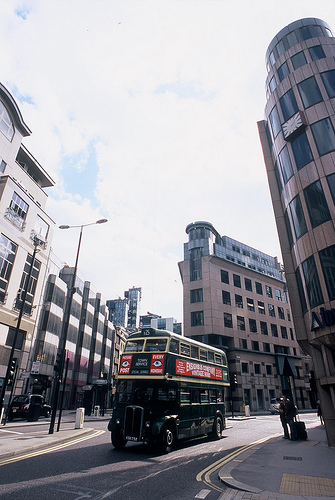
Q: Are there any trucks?
A: No, there are no trucks.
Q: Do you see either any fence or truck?
A: No, there are no trucks or fences.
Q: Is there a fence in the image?
A: No, there are no fences.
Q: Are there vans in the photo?
A: No, there are no vans.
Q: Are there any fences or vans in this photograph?
A: No, there are no vans or fences.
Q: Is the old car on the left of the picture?
A: Yes, the car is on the left of the image.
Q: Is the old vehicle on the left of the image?
A: Yes, the car is on the left of the image.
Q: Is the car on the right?
A: No, the car is on the left of the image.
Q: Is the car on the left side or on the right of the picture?
A: The car is on the left of the image.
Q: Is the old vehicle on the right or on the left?
A: The car is on the left of the image.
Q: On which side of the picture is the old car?
A: The car is on the left of the image.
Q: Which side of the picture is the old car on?
A: The car is on the left of the image.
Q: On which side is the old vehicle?
A: The car is on the left of the image.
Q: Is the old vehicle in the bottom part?
A: Yes, the car is in the bottom of the image.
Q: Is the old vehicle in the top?
A: No, the car is in the bottom of the image.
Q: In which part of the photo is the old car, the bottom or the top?
A: The car is in the bottom of the image.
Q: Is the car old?
A: Yes, the car is old.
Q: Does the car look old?
A: Yes, the car is old.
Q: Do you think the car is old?
A: Yes, the car is old.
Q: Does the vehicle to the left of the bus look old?
A: Yes, the car is old.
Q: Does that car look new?
A: No, the car is old.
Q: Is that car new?
A: No, the car is old.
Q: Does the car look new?
A: No, the car is old.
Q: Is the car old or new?
A: The car is old.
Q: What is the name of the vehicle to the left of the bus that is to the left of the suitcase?
A: The vehicle is a car.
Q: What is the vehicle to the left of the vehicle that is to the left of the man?
A: The vehicle is a car.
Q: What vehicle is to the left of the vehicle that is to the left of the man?
A: The vehicle is a car.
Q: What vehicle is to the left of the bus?
A: The vehicle is a car.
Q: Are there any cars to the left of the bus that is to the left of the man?
A: Yes, there is a car to the left of the bus.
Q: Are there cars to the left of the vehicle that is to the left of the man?
A: Yes, there is a car to the left of the bus.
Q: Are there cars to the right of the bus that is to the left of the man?
A: No, the car is to the left of the bus.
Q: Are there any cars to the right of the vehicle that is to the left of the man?
A: No, the car is to the left of the bus.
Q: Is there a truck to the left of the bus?
A: No, there is a car to the left of the bus.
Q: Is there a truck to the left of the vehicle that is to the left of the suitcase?
A: No, there is a car to the left of the bus.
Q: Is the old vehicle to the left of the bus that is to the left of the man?
A: Yes, the car is to the left of the bus.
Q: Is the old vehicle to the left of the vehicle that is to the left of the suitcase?
A: Yes, the car is to the left of the bus.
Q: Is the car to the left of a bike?
A: No, the car is to the left of the bus.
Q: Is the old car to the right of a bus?
A: No, the car is to the left of a bus.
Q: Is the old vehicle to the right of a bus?
A: No, the car is to the left of a bus.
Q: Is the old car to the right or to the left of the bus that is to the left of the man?
A: The car is to the left of the bus.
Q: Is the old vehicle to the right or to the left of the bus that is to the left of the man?
A: The car is to the left of the bus.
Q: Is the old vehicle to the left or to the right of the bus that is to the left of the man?
A: The car is to the left of the bus.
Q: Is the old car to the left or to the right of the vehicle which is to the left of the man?
A: The car is to the left of the bus.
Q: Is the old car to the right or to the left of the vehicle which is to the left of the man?
A: The car is to the left of the bus.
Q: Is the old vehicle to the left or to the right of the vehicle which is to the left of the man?
A: The car is to the left of the bus.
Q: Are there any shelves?
A: No, there are no shelves.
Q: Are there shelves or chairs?
A: No, there are no shelves or chairs.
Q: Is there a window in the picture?
A: Yes, there are windows.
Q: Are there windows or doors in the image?
A: Yes, there are windows.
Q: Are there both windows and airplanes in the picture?
A: No, there are windows but no airplanes.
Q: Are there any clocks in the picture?
A: Yes, there is a clock.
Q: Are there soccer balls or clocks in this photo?
A: Yes, there is a clock.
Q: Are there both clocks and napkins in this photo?
A: No, there is a clock but no napkins.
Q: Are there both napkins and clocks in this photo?
A: No, there is a clock but no napkins.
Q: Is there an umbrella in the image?
A: No, there are no umbrellas.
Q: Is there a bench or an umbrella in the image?
A: No, there are no umbrellas or benches.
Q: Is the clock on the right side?
A: Yes, the clock is on the right of the image.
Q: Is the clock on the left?
A: No, the clock is on the right of the image.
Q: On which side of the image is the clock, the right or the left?
A: The clock is on the right of the image.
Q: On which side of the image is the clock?
A: The clock is on the right of the image.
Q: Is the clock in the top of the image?
A: Yes, the clock is in the top of the image.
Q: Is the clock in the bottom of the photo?
A: No, the clock is in the top of the image.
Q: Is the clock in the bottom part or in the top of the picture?
A: The clock is in the top of the image.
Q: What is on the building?
A: The clock is on the building.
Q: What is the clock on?
A: The clock is on the building.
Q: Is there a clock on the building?
A: Yes, there is a clock on the building.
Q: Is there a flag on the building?
A: No, there is a clock on the building.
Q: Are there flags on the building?
A: No, there is a clock on the building.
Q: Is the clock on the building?
A: Yes, the clock is on the building.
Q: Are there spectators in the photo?
A: No, there are no spectators.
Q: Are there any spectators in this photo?
A: No, there are no spectators.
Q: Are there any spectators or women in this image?
A: No, there are no spectators or women.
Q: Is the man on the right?
A: Yes, the man is on the right of the image.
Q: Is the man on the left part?
A: No, the man is on the right of the image.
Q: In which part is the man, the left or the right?
A: The man is on the right of the image.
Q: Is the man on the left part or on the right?
A: The man is on the right of the image.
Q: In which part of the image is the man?
A: The man is on the right of the image.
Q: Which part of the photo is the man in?
A: The man is on the right of the image.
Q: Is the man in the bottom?
A: Yes, the man is in the bottom of the image.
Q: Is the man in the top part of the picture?
A: No, the man is in the bottom of the image.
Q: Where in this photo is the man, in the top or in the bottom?
A: The man is in the bottom of the image.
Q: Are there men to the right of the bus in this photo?
A: Yes, there is a man to the right of the bus.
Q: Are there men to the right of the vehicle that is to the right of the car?
A: Yes, there is a man to the right of the bus.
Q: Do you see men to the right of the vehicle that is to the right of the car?
A: Yes, there is a man to the right of the bus.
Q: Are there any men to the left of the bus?
A: No, the man is to the right of the bus.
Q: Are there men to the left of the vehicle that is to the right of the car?
A: No, the man is to the right of the bus.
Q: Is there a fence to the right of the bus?
A: No, there is a man to the right of the bus.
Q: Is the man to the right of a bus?
A: Yes, the man is to the right of a bus.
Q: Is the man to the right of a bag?
A: No, the man is to the right of a bus.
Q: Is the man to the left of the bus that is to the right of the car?
A: No, the man is to the right of the bus.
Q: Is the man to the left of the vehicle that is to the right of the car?
A: No, the man is to the right of the bus.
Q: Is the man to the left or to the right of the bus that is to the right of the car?
A: The man is to the right of the bus.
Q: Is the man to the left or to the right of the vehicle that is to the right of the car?
A: The man is to the right of the bus.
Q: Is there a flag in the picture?
A: No, there are no flags.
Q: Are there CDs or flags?
A: No, there are no flags or cds.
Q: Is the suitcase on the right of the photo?
A: Yes, the suitcase is on the right of the image.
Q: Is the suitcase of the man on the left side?
A: No, the suitcase is on the right of the image.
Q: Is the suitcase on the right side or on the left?
A: The suitcase is on the right of the image.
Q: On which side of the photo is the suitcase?
A: The suitcase is on the right of the image.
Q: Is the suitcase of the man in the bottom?
A: Yes, the suitcase is in the bottom of the image.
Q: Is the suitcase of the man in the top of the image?
A: No, the suitcase is in the bottom of the image.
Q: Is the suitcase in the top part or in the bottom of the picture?
A: The suitcase is in the bottom of the image.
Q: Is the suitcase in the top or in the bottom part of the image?
A: The suitcase is in the bottom of the image.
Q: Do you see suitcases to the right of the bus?
A: Yes, there is a suitcase to the right of the bus.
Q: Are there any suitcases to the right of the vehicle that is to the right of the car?
A: Yes, there is a suitcase to the right of the bus.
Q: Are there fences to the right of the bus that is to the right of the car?
A: No, there is a suitcase to the right of the bus.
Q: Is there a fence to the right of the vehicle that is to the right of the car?
A: No, there is a suitcase to the right of the bus.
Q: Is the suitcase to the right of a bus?
A: Yes, the suitcase is to the right of a bus.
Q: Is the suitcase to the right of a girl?
A: No, the suitcase is to the right of a bus.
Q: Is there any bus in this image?
A: Yes, there is a bus.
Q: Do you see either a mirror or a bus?
A: Yes, there is a bus.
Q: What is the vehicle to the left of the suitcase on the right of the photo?
A: The vehicle is a bus.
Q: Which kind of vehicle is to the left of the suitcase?
A: The vehicle is a bus.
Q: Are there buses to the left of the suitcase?
A: Yes, there is a bus to the left of the suitcase.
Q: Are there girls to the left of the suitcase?
A: No, there is a bus to the left of the suitcase.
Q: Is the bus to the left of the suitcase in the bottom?
A: Yes, the bus is to the left of the suitcase.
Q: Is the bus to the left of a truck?
A: No, the bus is to the left of the suitcase.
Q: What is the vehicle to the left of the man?
A: The vehicle is a bus.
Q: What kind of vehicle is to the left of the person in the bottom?
A: The vehicle is a bus.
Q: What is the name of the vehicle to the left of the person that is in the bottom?
A: The vehicle is a bus.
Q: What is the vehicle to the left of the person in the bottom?
A: The vehicle is a bus.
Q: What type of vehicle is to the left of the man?
A: The vehicle is a bus.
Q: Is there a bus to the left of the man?
A: Yes, there is a bus to the left of the man.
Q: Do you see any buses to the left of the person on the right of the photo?
A: Yes, there is a bus to the left of the man.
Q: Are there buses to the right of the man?
A: No, the bus is to the left of the man.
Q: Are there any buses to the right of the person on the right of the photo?
A: No, the bus is to the left of the man.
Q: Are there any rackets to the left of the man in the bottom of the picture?
A: No, there is a bus to the left of the man.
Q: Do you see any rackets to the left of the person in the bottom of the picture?
A: No, there is a bus to the left of the man.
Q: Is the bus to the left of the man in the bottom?
A: Yes, the bus is to the left of the man.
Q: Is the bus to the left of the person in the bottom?
A: Yes, the bus is to the left of the man.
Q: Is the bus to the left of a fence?
A: No, the bus is to the left of the man.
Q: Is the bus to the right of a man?
A: No, the bus is to the left of a man.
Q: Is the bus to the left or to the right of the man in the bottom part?
A: The bus is to the left of the man.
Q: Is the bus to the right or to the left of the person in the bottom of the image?
A: The bus is to the left of the man.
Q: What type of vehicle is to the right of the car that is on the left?
A: The vehicle is a bus.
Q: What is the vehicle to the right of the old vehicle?
A: The vehicle is a bus.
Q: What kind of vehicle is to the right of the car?
A: The vehicle is a bus.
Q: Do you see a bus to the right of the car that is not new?
A: Yes, there is a bus to the right of the car.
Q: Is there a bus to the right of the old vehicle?
A: Yes, there is a bus to the right of the car.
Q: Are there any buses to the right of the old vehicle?
A: Yes, there is a bus to the right of the car.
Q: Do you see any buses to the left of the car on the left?
A: No, the bus is to the right of the car.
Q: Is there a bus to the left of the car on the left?
A: No, the bus is to the right of the car.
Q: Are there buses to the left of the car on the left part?
A: No, the bus is to the right of the car.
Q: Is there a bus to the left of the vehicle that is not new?
A: No, the bus is to the right of the car.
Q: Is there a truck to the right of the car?
A: No, there is a bus to the right of the car.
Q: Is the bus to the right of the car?
A: Yes, the bus is to the right of the car.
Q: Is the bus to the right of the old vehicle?
A: Yes, the bus is to the right of the car.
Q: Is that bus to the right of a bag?
A: No, the bus is to the right of the car.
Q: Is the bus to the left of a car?
A: No, the bus is to the right of a car.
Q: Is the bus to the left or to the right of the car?
A: The bus is to the right of the car.